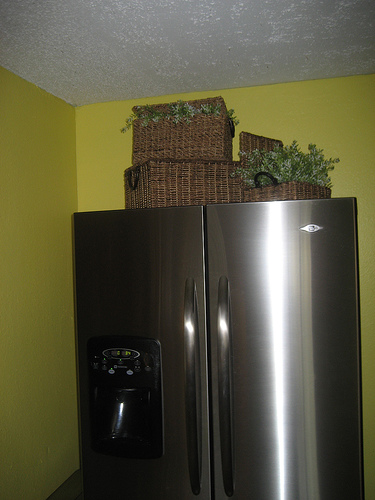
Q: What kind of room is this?
A: Kitchen.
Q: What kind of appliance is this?
A: Stainless steel refrigerator.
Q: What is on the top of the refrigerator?
A: Wicker baskets.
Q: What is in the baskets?
A: Green plants.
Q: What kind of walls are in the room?
A: Yellow walls.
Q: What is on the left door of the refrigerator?
A: Water and ice maker.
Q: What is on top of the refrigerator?
A: Baskets.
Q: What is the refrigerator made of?
A: Stainless steel.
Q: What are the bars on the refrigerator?
A: Handles.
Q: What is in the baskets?
A: Plants.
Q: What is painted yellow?
A: Walls.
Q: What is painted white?
A: Ceiling.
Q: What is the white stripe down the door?
A: Reflection.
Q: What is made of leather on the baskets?
A: Handles.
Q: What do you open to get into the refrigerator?
A: Doors.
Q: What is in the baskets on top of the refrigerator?
A: Green plants.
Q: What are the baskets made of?
A: Brown wicker material.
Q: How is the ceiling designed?
A: White popcorn style.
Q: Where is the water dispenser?
A: Left side of refrigerator.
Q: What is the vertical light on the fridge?
A: Camera glare.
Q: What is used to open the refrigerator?
A: Two long handles on doors.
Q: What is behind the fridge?
A: Yellow wall.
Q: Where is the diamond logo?
A: Upper right of fridge.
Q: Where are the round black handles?
A: Sides of brown baskets.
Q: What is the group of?
A: Wicker baskets.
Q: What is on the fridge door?
A: A reflection.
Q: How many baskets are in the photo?
A: 3.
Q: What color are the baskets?
A: Brown.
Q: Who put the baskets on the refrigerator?
A: The boss.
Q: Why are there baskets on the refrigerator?
A: To keep them away from the kids.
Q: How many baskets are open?
A: One.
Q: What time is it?
A: Noon.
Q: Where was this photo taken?
A: The kitchen.